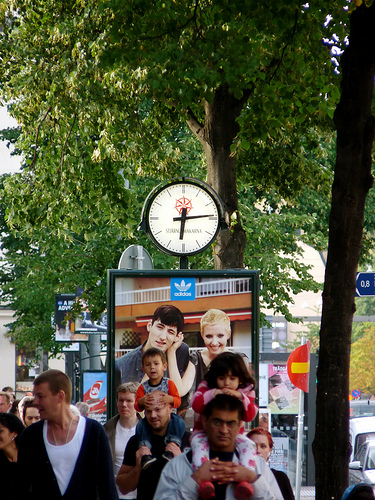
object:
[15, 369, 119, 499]
man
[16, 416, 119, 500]
black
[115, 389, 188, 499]
man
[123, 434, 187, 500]
black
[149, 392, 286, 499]
man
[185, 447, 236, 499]
black